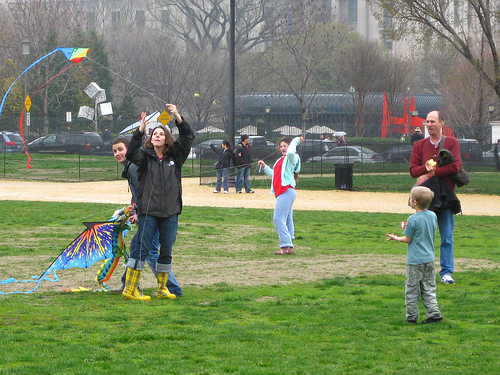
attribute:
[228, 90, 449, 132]
house — in the background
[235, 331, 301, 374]
grass — short, green, yellow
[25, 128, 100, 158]
car — black 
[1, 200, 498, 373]
grass — short, green, yellow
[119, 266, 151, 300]
boot — yellow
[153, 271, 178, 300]
boot — yellow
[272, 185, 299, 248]
pants — Blue 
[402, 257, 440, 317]
pants — khaki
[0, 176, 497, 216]
path — dirt 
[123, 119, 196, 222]
jacket — black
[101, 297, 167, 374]
grass — short, green, yellow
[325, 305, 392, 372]
grass — short, green, yellow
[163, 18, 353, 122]
trees — in the background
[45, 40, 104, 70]
kite — multi colored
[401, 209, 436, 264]
shirt — blue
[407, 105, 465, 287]
shirt — red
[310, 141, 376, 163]
gray car — grey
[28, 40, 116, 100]
kite — in the air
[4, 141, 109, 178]
fencing — black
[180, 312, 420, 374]
grass — short, green, yellow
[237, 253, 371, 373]
grass — green , yellow 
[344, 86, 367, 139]
train — black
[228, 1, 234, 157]
pole — black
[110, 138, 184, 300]
man — young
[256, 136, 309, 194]
coat — blue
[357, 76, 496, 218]
coat — black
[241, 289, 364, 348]
grass — short, yellow, green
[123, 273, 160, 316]
boots — yellow